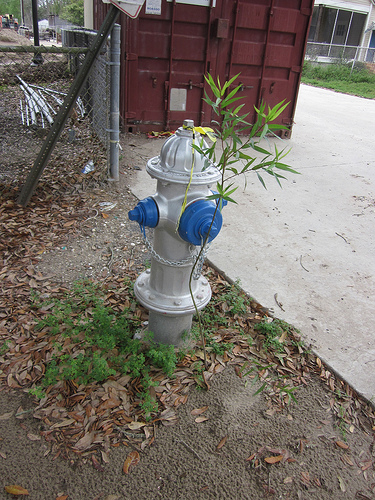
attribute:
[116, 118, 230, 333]
hydrant — silver, chained, blue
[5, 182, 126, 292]
leaves — dried, dead, piled, brown, green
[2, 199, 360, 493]
ground — dirty, dented, concrete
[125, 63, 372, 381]
driveway — concrete, gray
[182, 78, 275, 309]
plant — green, growing, tall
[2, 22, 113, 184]
fence — metal, linked, chain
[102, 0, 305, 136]
dumpster — big, maroon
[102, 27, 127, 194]
pole — metal, leaning, iron, gray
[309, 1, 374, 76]
porch — screened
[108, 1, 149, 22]
sign — white, red, tipped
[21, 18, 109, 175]
pipe — laying, mossy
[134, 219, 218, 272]
chain — hooked, hanging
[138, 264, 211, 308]
bolts — silver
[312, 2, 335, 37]
window — glass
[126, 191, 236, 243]
plugs — blue